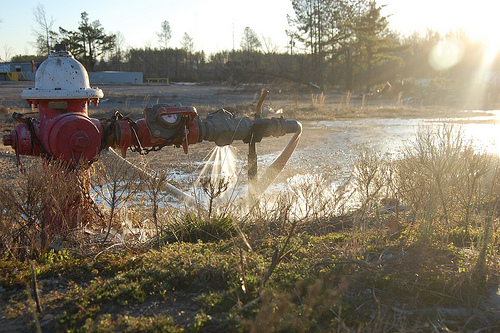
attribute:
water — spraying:
[200, 145, 242, 189]